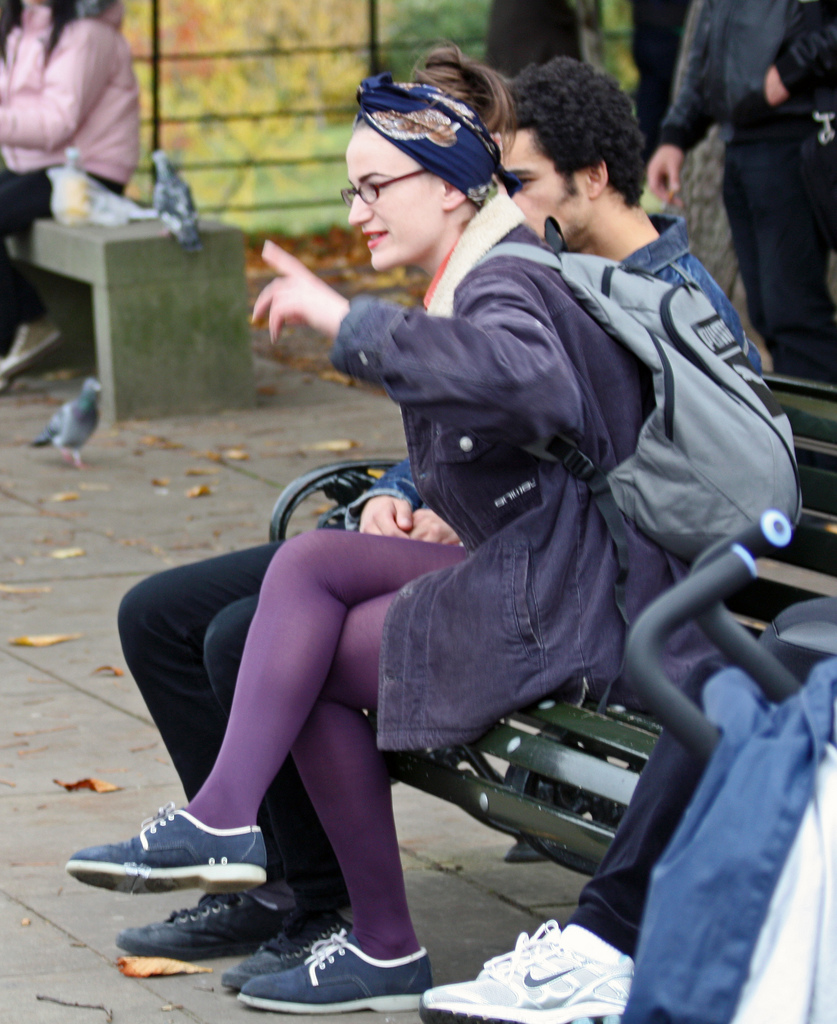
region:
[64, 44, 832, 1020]
woman and a man seated on a bench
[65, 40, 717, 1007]
woman's head has a wrapping tied around it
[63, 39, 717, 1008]
woman is making a gesture with her left hand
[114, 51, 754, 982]
man's hair is curly and very dark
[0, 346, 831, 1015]
ground is paved with large grey stone tiles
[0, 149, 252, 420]
pigeon perched on the edge of a stone bench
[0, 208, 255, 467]
pigeon standing in front of bench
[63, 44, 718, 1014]
woman's shoes are blue and white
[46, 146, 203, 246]
pigeon is perched near a white bag with a container in it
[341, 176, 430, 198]
The eyeglasses the girl is wearing.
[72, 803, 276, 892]
The left shoe on the girl's foot.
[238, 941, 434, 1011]
The right shoe the girl is wearing.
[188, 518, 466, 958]
The purple stockings the girl is wearing.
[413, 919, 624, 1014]
The Nike tennis shoe the person on the right is wearing.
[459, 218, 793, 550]
The back pack the girl is carrying.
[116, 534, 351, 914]
The black pants the guy sitting next to the girl is wearing.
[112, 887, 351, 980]
The black sneakers the guy is wearing.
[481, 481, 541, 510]
The white writing on the girl's coat.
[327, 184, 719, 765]
The coat the girl in purple stockings is wearing.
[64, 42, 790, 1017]
A man and a woman sitting on a bench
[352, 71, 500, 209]
Bandana wrapped around the woman's head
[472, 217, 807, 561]
Backpack on the woman's back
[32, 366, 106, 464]
Pigeon on the ground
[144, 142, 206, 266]
A pigeon on the bench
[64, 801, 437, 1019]
Blue shoes on the woman's feet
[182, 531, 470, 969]
Purple tights on the woman's legs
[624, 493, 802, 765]
Handles of a stroller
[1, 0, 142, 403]
Person in a pink jacket sitting on the bench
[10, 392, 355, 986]
Fallen leaves on the ground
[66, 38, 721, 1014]
woman with legs crossed wearing purple tights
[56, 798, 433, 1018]
pair of blue and white shoes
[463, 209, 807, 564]
black and grey backpack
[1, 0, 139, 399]
woman sitting wearing a pink coat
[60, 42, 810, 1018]
young man and woman sitting next to each other on a bench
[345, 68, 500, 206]
navy blue decorative head wrap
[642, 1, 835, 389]
man in background wearing leather coat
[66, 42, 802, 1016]
woman wearing purple jean coat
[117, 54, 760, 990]
man with curly black hair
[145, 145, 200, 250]
pigeon perched on a bench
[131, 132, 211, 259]
Pigeon sitting on stone bench.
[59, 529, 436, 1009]
Woman's purple tights and blue shoes.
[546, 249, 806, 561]
Grey backpack on woman's back.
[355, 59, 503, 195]
Blue patterned bandanna in woman's hair.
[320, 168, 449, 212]
Glasses on woman's face.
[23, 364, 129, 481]
Pigeon walking on sidewalk.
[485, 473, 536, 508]
Writing on jacket pocket.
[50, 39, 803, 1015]
Man and woman sitting on park bench.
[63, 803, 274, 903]
Shoe on a woman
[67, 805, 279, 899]
Blue shoe on a woman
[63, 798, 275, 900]
Blue and white shoe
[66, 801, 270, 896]
Blue and white shoe on a woman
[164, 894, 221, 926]
Laces on a shoe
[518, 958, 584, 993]
Nike logo on a shoe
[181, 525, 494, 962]
purple tights on legs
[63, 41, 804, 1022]
woman wearing purple tights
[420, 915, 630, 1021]
white and grey sneaker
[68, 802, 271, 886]
blue and white shoe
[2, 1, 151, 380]
female in a pink coat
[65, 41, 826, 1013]
two people sitting on a bench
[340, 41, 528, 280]
woman with a headband